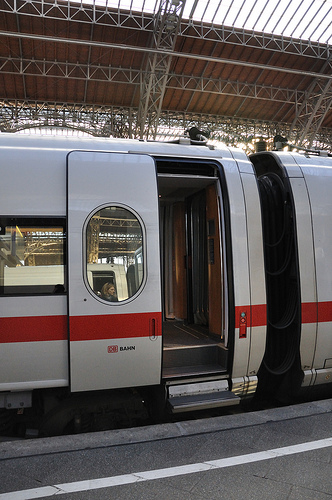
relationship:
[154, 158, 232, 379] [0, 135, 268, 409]
door on train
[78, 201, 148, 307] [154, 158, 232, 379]
window on door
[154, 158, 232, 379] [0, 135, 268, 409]
door outside train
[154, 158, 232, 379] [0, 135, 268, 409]
door on top train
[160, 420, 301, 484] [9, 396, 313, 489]
paint on top ground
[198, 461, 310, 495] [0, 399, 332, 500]
cracks in ground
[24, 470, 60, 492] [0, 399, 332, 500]
cracks in ground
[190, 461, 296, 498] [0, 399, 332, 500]
cracks in ground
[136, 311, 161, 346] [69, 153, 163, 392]
handle on door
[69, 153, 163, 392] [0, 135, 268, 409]
door on train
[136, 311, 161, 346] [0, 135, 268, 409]
handle on train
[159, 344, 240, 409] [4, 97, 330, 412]
stairs on train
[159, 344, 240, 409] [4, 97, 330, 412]
stairs below train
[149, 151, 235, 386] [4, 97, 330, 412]
doorway inside train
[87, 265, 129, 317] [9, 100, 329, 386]
woman outside train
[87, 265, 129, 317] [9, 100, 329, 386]
woman behind train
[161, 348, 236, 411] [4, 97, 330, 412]
steps below train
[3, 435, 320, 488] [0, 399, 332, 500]
line on ground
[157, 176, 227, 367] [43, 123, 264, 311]
hallway in train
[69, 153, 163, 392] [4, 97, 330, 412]
door on train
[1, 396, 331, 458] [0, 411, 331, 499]
curb on sidewalk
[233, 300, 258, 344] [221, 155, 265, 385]
buttons on train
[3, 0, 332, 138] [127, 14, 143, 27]
bridge has truss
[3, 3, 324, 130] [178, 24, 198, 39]
bridge has truss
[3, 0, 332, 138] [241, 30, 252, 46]
bridge has truss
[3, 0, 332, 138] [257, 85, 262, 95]
bridge has truss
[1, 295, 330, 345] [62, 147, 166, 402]
stripe on door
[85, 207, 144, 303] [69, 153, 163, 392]
glass in door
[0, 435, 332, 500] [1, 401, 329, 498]
line on concrete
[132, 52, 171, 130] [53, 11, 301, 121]
metal beam in ceiling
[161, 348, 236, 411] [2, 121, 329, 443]
steps on train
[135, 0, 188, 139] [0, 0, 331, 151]
cables in ceiling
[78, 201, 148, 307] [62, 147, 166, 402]
window in door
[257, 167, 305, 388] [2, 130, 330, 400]
hose middle train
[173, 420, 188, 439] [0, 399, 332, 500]
marks on ground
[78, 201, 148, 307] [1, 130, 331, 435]
window on car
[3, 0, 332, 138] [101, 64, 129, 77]
bridge has truss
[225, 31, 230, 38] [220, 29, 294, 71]
truss of bridge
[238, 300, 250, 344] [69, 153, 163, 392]
buttons on door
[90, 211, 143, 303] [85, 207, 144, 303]
reflection in glass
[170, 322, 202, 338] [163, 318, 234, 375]
marks on floor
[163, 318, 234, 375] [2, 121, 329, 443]
floor of train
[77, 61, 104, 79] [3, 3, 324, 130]
truss of bridge